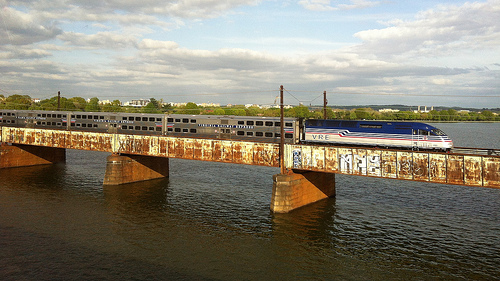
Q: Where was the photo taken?
A: By the water.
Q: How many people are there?
A: 0.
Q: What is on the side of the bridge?
A: Graffiti.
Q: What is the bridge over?
A: A river.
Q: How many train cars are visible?
A: 4.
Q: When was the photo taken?
A: Daytime.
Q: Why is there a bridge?
A: So the train can travel.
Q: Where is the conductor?
A: On the front train car.